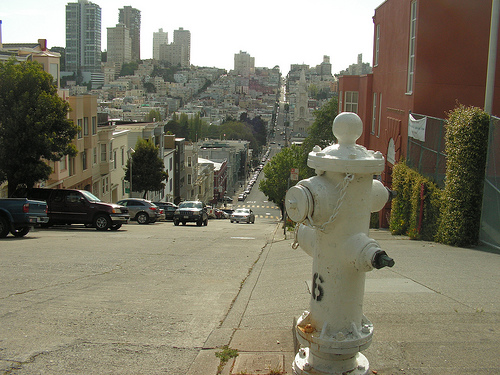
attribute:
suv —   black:
[173, 200, 210, 227]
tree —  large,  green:
[5, 57, 75, 184]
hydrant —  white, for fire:
[278, 113, 400, 369]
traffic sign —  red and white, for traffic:
[283, 162, 310, 190]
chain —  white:
[305, 171, 354, 227]